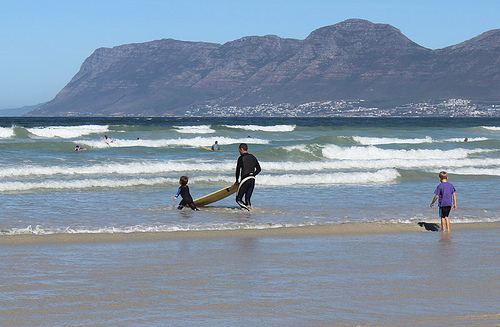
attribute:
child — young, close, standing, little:
[419, 159, 488, 246]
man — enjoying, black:
[226, 138, 269, 212]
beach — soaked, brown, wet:
[20, 194, 479, 326]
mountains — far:
[151, 26, 427, 91]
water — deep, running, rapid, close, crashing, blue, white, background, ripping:
[265, 119, 402, 187]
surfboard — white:
[198, 174, 237, 223]